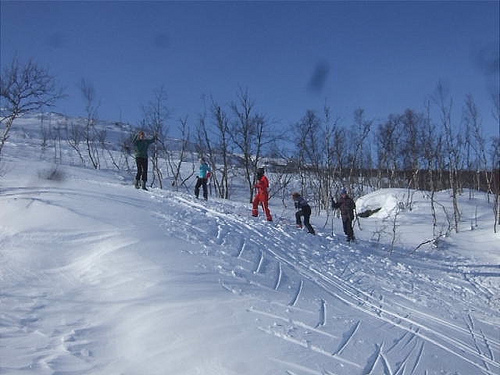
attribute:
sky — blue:
[3, 2, 493, 176]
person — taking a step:
[291, 190, 314, 235]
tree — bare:
[325, 115, 350, 197]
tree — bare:
[285, 126, 317, 188]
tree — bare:
[362, 125, 421, 191]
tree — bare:
[236, 89, 255, 189]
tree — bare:
[432, 99, 469, 189]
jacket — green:
[137, 133, 155, 152]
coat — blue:
[193, 152, 225, 197]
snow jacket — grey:
[122, 132, 164, 160]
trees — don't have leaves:
[216, 99, 483, 181]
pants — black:
[187, 178, 212, 205]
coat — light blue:
[195, 165, 210, 178]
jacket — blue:
[195, 168, 213, 176]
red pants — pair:
[250, 194, 275, 222]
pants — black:
[295, 210, 315, 231]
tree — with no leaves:
[431, 89, 464, 241]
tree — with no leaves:
[461, 97, 498, 202]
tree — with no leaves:
[395, 114, 428, 193]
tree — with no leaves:
[350, 122, 377, 204]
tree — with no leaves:
[315, 117, 352, 204]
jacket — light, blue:
[192, 159, 211, 179]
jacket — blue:
[194, 160, 214, 180]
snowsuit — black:
[332, 195, 362, 235]